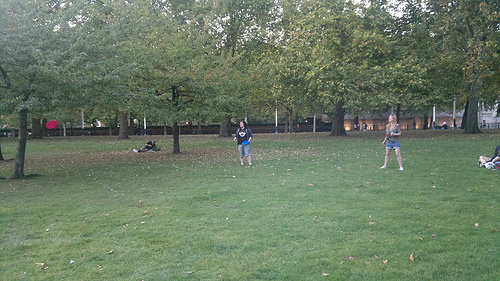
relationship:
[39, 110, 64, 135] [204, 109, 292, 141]
frisbee flying through air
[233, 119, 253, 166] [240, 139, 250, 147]
girl holding frisbee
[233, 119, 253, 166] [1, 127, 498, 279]
girl standing grass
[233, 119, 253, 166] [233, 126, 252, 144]
girl wearing black top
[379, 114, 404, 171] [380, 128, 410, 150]
girl wearing shorts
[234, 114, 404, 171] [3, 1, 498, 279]
people in park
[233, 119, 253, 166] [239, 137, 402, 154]
girl wearing shorts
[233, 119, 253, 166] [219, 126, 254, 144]
girl wearing jacket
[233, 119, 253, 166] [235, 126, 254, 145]
girl wearing jacket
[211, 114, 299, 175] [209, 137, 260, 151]
girl wearing shorts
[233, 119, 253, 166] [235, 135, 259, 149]
girl holding frisbee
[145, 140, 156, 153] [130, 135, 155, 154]
man behind girls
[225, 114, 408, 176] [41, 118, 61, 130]
people playing frisbee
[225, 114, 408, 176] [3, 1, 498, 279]
people in park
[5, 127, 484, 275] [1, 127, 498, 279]
field of grass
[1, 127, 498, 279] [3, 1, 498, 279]
grass in park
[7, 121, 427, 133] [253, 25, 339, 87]
fence behind trees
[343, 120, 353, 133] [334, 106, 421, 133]
lights from building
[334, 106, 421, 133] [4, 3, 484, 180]
building behind trees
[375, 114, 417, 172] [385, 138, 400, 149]
girl with jeans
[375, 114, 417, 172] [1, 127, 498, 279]
girl on grass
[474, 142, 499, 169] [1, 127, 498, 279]
person on grass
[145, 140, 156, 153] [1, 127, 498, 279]
man on grass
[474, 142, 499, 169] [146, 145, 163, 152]
person with belongings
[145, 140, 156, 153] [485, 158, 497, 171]
man with belongings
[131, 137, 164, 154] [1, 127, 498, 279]
people on grass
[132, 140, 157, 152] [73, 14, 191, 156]
people under tree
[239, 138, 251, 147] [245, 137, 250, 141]
frisbee in hand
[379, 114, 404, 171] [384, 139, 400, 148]
girl wearing jeans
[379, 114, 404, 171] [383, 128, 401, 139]
girl with shirt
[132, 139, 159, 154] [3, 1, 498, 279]
man in park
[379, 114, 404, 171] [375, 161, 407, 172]
girl with shoes